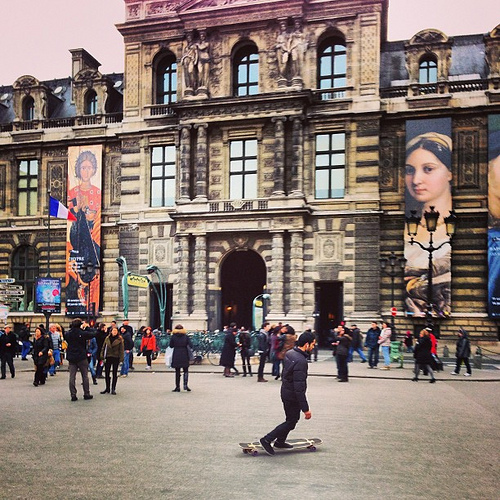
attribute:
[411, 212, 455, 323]
lamp post — black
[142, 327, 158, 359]
jacket — red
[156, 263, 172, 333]
pole — green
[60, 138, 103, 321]
painting — big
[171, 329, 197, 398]
jacket — black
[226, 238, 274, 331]
entry — rounded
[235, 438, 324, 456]
skateboard — black, long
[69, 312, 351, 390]
people — standing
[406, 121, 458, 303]
artwork — tall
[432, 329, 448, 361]
coat — red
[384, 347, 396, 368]
pants — blue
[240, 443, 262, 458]
wheels — purple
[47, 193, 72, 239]
flag — waving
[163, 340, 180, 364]
bag — white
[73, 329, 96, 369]
coat — black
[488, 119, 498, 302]
banner — big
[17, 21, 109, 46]
sky — pink, overcast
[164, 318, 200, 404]
person — standing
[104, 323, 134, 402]
person — standing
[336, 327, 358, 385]
person — standing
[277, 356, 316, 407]
jacket — down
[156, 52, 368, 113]
windows — large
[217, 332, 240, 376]
coat — black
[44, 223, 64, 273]
flagpole — metal